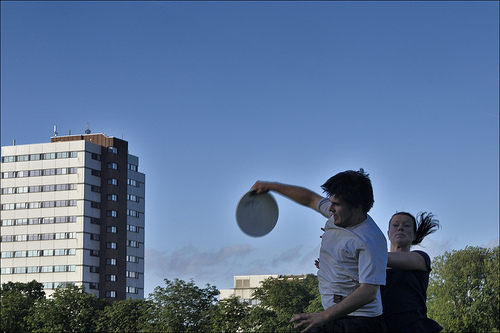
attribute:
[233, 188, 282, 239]
frisbee — white, circular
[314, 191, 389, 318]
tee shirt — white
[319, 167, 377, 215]
hair — black, short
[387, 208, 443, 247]
hair — black, ponytail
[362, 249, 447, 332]
shirt — black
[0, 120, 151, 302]
building — high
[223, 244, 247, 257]
cloud — white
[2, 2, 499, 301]
sky — blue